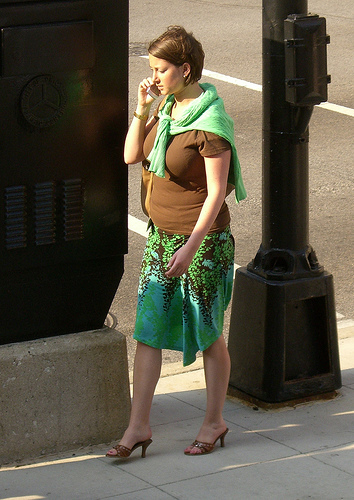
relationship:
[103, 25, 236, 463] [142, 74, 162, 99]
woman on phone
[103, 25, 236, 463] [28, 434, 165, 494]
woman at sidewalk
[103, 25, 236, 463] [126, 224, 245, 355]
woman wearing skirt